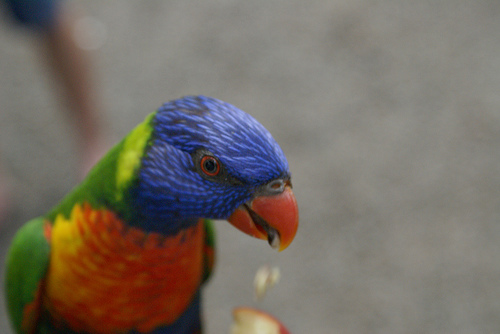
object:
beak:
[224, 187, 300, 252]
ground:
[306, 155, 350, 192]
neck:
[82, 144, 194, 230]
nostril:
[265, 179, 286, 193]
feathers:
[52, 263, 151, 313]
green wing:
[1, 216, 52, 334]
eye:
[200, 155, 220, 177]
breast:
[76, 233, 184, 298]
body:
[40, 204, 205, 334]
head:
[83, 91, 300, 251]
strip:
[115, 111, 156, 204]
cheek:
[135, 176, 222, 220]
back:
[46, 135, 126, 218]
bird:
[0, 93, 297, 334]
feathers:
[139, 93, 291, 223]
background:
[297, 0, 500, 232]